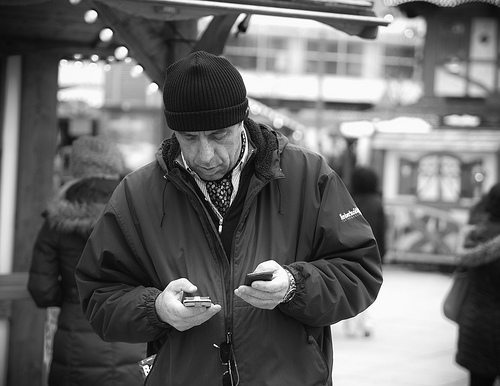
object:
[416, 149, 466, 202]
windows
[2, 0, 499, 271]
building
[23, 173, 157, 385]
jacket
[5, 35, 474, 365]
message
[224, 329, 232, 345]
zipper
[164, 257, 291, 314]
phones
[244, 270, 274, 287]
cell phones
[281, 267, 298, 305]
watch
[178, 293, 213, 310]
object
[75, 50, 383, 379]
man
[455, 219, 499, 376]
jacket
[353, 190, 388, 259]
jacket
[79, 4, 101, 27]
lights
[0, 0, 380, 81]
awning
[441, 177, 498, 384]
person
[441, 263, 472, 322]
bag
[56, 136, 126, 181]
bonnet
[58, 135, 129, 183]
head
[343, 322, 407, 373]
ground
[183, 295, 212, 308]
cell phone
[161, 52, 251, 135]
hat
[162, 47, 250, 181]
head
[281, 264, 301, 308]
wrist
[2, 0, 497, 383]
photo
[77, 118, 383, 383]
jacket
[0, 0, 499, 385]
city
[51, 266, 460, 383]
sidewalk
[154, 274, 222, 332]
hands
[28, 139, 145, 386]
person